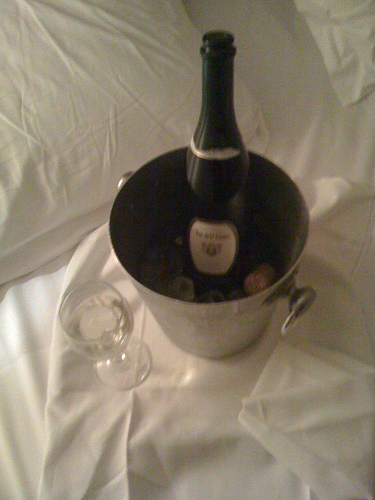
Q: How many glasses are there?
A: One.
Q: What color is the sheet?
A: White.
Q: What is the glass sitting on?
A: A sheet.